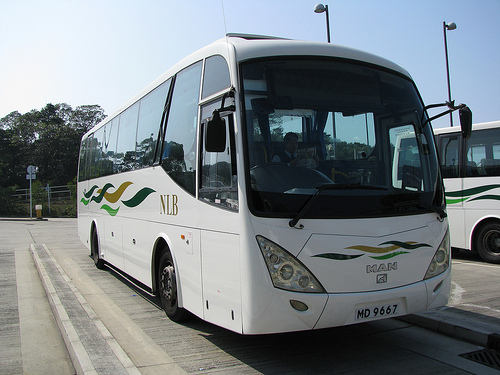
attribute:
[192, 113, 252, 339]
door — exit, passenger, entrance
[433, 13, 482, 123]
poles — light, distant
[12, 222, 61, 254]
street — corner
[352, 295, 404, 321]
plate — license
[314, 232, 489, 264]
design — decorative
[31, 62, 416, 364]
bus — white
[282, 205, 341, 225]
wiper — window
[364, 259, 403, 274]
logo — silver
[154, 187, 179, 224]
logo — silver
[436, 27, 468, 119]
post — lamp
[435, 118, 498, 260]
bus — white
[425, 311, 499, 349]
curb — cement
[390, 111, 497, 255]
bus — large, white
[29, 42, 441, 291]
bus — big, white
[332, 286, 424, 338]
plate — license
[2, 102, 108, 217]
trees — distant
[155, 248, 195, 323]
front wheel — white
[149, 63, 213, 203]
window — large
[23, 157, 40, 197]
sign — traffic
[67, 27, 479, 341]
bus — side,  Large,  white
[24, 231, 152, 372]
stripes — small